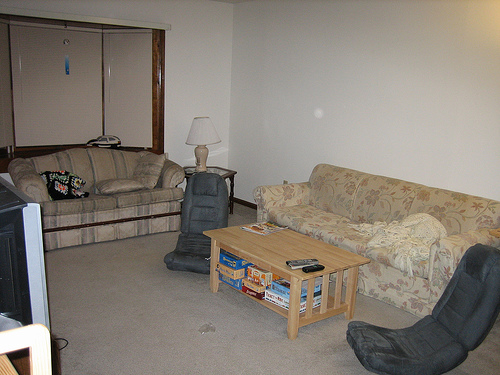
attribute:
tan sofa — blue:
[6, 148, 198, 249]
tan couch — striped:
[5, 145, 201, 248]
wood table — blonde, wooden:
[195, 218, 371, 337]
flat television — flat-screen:
[0, 175, 53, 336]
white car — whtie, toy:
[85, 135, 121, 146]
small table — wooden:
[180, 164, 237, 215]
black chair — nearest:
[348, 230, 493, 374]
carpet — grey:
[42, 191, 499, 367]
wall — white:
[2, 2, 499, 219]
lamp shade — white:
[184, 113, 226, 145]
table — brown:
[181, 160, 236, 215]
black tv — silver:
[0, 174, 57, 335]